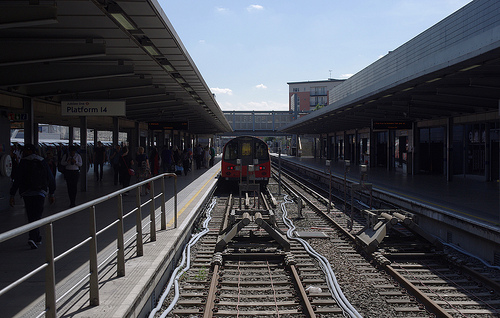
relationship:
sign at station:
[56, 90, 132, 123] [14, 11, 227, 243]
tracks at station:
[202, 190, 314, 316] [14, 4, 496, 305]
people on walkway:
[7, 113, 223, 228] [79, 155, 219, 269]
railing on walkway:
[11, 187, 176, 303] [13, 132, 213, 301]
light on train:
[228, 164, 233, 169] [221, 135, 269, 192]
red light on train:
[257, 165, 262, 170] [217, 133, 272, 187]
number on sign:
[11, 85, 139, 177] [56, 102, 118, 124]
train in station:
[220, 135, 274, 194] [14, 4, 496, 305]